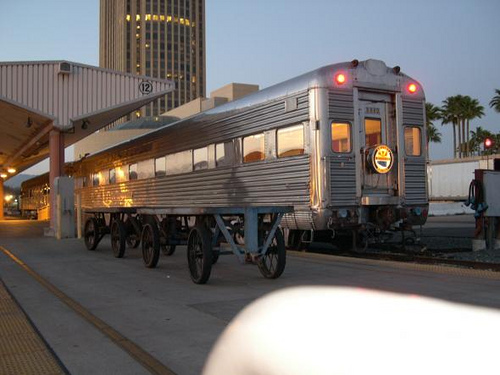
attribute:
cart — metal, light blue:
[83, 206, 295, 285]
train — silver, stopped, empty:
[21, 59, 431, 252]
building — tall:
[100, 1, 207, 134]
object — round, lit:
[368, 145, 394, 174]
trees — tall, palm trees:
[426, 88, 500, 162]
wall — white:
[427, 153, 499, 217]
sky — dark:
[0, 0, 500, 177]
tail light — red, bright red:
[334, 71, 347, 86]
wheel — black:
[186, 225, 213, 283]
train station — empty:
[1, 60, 500, 373]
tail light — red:
[407, 83, 418, 95]